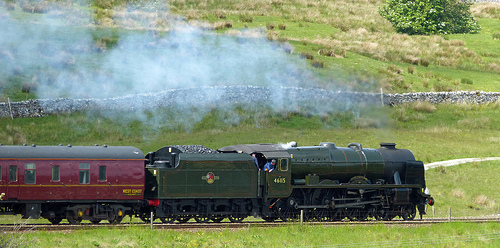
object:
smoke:
[9, 10, 384, 137]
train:
[0, 140, 436, 225]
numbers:
[274, 175, 287, 184]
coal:
[171, 144, 219, 154]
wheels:
[402, 202, 417, 220]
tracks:
[0, 218, 500, 232]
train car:
[1, 144, 151, 223]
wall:
[0, 84, 497, 119]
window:
[99, 165, 109, 182]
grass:
[0, 0, 500, 103]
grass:
[0, 224, 500, 248]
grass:
[419, 70, 434, 79]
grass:
[297, 23, 308, 28]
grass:
[419, 126, 455, 134]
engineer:
[262, 159, 276, 173]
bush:
[382, 0, 477, 35]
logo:
[201, 172, 220, 185]